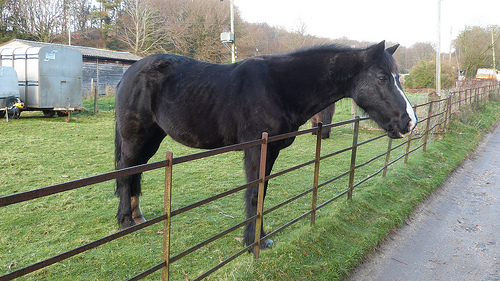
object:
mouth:
[386, 123, 413, 139]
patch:
[389, 72, 418, 133]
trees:
[280, 18, 316, 51]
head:
[349, 39, 419, 139]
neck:
[271, 42, 360, 126]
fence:
[0, 77, 500, 281]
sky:
[0, 0, 128, 36]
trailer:
[0, 47, 86, 122]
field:
[0, 94, 500, 279]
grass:
[0, 94, 500, 281]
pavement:
[344, 121, 500, 281]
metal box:
[220, 31, 235, 44]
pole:
[228, 0, 236, 63]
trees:
[111, 0, 172, 56]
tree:
[455, 27, 500, 87]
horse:
[111, 38, 419, 255]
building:
[0, 37, 145, 97]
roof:
[0, 38, 145, 62]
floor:
[350, 122, 500, 281]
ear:
[386, 43, 401, 55]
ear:
[364, 39, 386, 51]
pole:
[435, 0, 441, 99]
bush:
[403, 59, 458, 89]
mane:
[285, 42, 379, 57]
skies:
[229, 0, 500, 54]